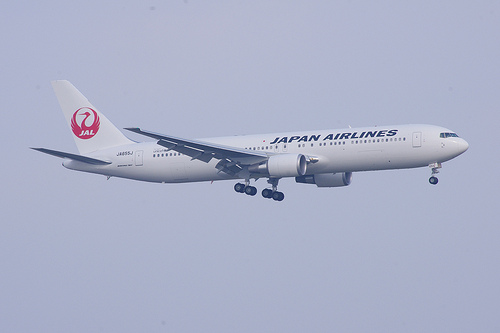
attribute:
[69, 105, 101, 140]
logo — airline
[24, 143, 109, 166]
stabilizer — horizontal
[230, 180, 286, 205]
tires — black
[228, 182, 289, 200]
tires — down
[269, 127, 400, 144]
words — black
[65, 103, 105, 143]
emblem — red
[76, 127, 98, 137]
letters — white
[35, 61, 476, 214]
passenger jet — commercial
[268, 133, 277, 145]
lettering — blue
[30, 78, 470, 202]
plane — flying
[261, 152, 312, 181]
engine — silver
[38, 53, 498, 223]
airplane — flying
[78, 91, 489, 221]
plane — white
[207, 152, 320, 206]
gear — landing